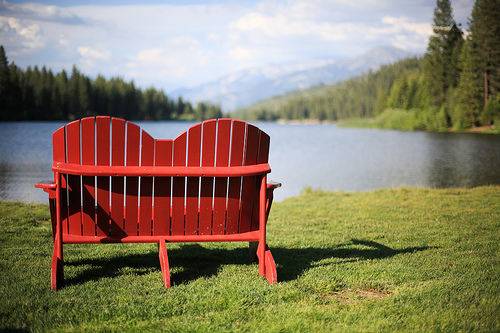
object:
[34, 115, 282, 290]
bench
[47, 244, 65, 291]
legs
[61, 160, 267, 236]
back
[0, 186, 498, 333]
grass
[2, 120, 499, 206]
water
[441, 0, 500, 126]
trees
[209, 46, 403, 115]
mountains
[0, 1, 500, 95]
sky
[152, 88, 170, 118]
tree